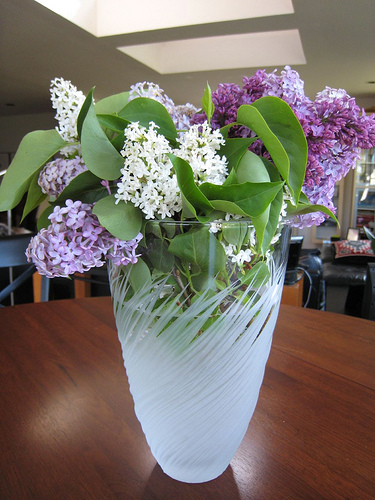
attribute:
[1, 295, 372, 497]
table — wooden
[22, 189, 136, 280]
flower — Light purple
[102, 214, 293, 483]
pot — glass, a flower pot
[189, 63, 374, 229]
flowers — purple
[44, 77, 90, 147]
flower — white, sticking up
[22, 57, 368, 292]
flowers — small, white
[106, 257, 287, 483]
vase — decorative, frosted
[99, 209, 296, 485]
vase — frosted glass, large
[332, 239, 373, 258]
pillow — red, designed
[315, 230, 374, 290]
couch — black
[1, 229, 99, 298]
chair — black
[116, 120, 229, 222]
flowers — white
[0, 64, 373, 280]
flowers — purple, white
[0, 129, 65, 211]
leaf — green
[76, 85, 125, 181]
leaf — green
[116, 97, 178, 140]
leaf — green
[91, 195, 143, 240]
leaf — green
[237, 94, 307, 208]
leaf — green